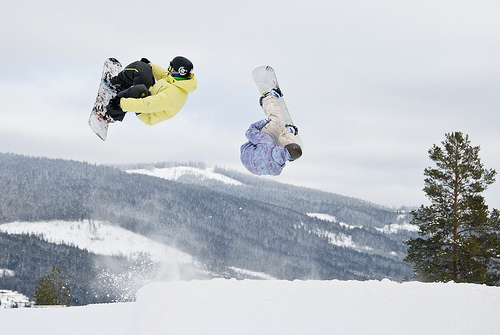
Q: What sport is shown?
A: Snowboarding.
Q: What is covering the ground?
A: Snow.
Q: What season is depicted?
A: Winter.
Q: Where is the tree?
A: Behind the hill.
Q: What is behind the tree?
A: A mountain.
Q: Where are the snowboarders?
A: In the air.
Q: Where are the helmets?
A: On the boarders' heads.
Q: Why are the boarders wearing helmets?
A: Safety.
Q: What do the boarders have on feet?
A: Boards.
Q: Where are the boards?
A: On the snowboarders' feet.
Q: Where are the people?
A: In a field of snow.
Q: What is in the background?
A: A tree in the snow.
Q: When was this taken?
A: During the day time.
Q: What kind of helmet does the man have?
A: A black helmet.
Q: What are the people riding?
A: They are riding snowboards.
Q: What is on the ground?
A: Snow.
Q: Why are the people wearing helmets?
A: Because they are riding snowboards.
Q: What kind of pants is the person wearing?
A: Black pants for the snow.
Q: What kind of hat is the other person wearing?
A: A brown hat.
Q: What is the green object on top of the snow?
A: A tree.